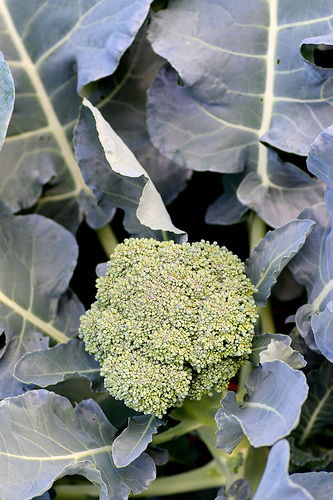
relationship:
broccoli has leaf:
[0, 3, 331, 499] [67, 96, 188, 244]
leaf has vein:
[67, 96, 188, 244] [96, 185, 143, 212]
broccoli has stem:
[0, 3, 331, 499] [178, 382, 235, 479]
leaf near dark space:
[67, 96, 188, 244] [112, 209, 126, 242]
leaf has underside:
[67, 96, 188, 244] [86, 102, 187, 242]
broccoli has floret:
[0, 3, 331, 499] [71, 233, 255, 428]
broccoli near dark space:
[0, 3, 331, 499] [112, 209, 126, 242]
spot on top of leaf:
[273, 56, 283, 68] [147, 3, 331, 234]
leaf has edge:
[67, 96, 188, 244] [69, 96, 88, 136]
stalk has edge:
[153, 420, 198, 449] [171, 426, 198, 438]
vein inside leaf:
[96, 185, 143, 212] [67, 96, 188, 244]